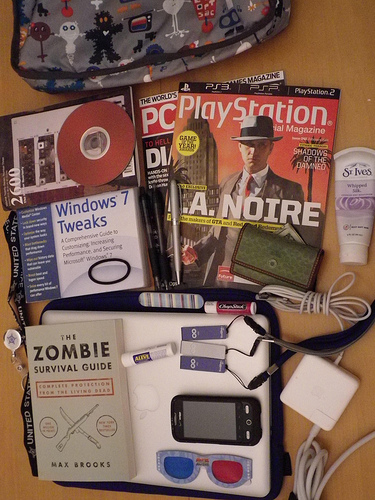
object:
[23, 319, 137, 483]
book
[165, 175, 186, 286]
ink pen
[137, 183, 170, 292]
ink pen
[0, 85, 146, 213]
magazines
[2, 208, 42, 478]
lanyard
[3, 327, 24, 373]
charm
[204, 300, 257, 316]
chapstick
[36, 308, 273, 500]
pc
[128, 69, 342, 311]
magazines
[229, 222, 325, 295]
billfold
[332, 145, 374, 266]
bottle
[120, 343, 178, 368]
white tube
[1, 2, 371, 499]
foreground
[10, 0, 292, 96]
bag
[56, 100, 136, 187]
cd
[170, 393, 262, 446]
black cellphone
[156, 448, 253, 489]
3d glasses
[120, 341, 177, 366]
pain medicine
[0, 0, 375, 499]
table